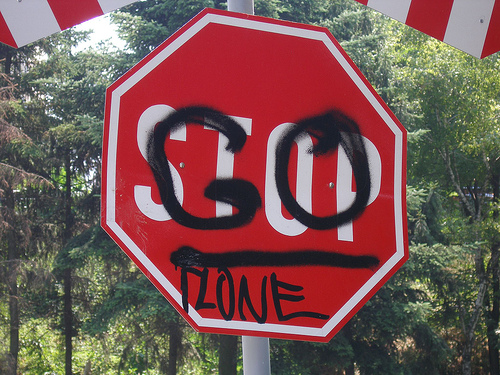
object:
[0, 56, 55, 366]
trees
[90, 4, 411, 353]
sign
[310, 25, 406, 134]
trim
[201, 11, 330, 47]
trim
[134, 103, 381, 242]
stop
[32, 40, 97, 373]
tree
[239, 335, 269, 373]
pole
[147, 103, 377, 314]
black writing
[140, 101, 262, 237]
letter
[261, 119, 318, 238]
letter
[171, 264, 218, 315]
letter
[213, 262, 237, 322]
letter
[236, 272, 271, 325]
letter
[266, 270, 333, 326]
letter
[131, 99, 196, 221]
letter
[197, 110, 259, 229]
letter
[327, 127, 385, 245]
letter